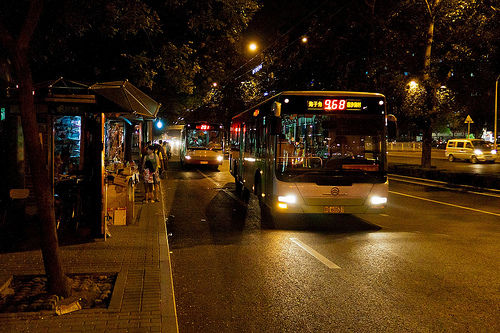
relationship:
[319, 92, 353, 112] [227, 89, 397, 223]
number on bus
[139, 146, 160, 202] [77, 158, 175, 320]
people on sidewalk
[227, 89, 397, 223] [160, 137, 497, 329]
bus on road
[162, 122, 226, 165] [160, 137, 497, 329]
bus on road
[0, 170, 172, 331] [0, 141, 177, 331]
brick on sidewalk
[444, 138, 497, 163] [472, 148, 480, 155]
car with headlight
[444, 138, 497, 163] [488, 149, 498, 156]
car with headlight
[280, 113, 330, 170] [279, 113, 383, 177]
reflections on windshield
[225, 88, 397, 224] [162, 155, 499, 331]
bus on road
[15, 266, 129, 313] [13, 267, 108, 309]
tree in square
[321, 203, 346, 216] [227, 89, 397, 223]
tag on bus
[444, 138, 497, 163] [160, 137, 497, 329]
car on road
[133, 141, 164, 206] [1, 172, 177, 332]
people on sidewalk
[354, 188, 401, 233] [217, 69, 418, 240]
lights on bus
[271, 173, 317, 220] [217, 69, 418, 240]
lights on bus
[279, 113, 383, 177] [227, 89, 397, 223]
windshield of bus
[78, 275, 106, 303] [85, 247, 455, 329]
rocks on ground